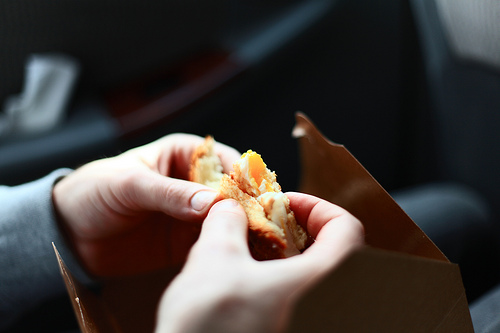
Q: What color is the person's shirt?
A: Gray.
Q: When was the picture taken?
A: When someone was eating.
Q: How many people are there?
A: 1.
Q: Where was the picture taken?
A: In a car.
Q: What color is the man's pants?
A: Blue.